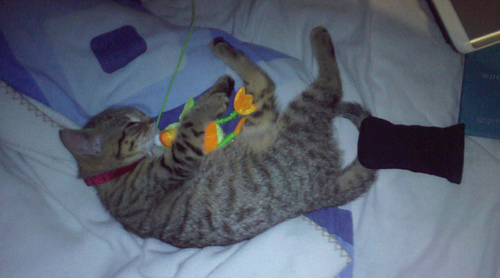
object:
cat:
[60, 26, 380, 246]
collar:
[83, 155, 147, 187]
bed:
[0, 0, 499, 278]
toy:
[156, 1, 259, 157]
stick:
[153, 1, 196, 128]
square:
[90, 24, 147, 75]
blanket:
[0, 78, 351, 277]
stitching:
[0, 77, 354, 263]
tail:
[332, 100, 379, 199]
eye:
[123, 121, 140, 130]